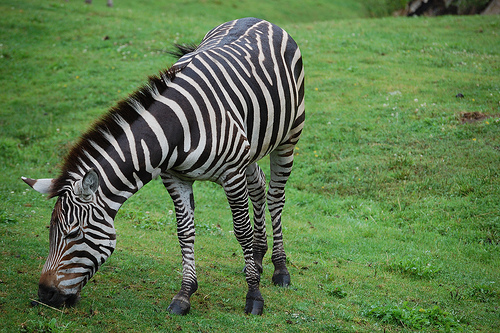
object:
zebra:
[21, 17, 318, 320]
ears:
[20, 169, 100, 196]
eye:
[62, 223, 81, 240]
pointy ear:
[72, 170, 102, 198]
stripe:
[210, 28, 283, 160]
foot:
[244, 287, 266, 315]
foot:
[168, 292, 195, 315]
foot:
[270, 256, 292, 287]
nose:
[38, 281, 68, 307]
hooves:
[164, 259, 299, 314]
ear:
[21, 169, 65, 198]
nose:
[38, 282, 59, 305]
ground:
[0, 0, 499, 331]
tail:
[165, 41, 193, 58]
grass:
[0, 2, 499, 331]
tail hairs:
[148, 36, 199, 61]